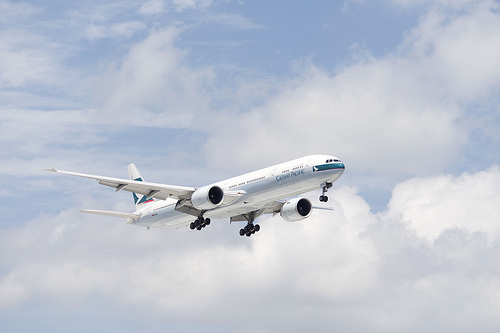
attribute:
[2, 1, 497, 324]
sky — cloudy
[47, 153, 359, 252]
airplane — white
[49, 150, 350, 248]
airplane — big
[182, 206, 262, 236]
tires — black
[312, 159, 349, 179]
front — blue